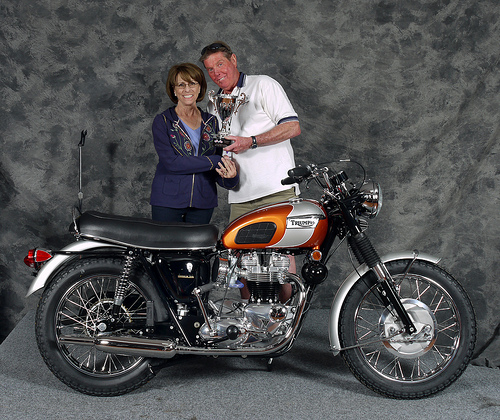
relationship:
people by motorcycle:
[154, 40, 300, 371] [21, 131, 479, 406]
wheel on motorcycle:
[28, 253, 177, 399] [21, 131, 479, 406]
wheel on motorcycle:
[335, 258, 479, 403] [21, 131, 479, 406]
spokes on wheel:
[56, 276, 151, 379] [28, 253, 177, 399]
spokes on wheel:
[356, 272, 467, 384] [335, 258, 479, 403]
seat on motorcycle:
[68, 209, 221, 256] [21, 131, 479, 406]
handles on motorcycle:
[281, 163, 322, 193] [21, 131, 479, 406]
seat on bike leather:
[68, 209, 221, 256] [101, 227, 189, 239]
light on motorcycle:
[355, 177, 392, 218] [21, 131, 479, 406]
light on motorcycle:
[22, 245, 56, 269] [21, 131, 479, 406]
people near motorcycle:
[154, 40, 300, 371] [21, 131, 479, 406]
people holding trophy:
[154, 40, 300, 371] [207, 87, 249, 151]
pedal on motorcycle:
[191, 279, 249, 347] [21, 131, 479, 406]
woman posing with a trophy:
[147, 59, 218, 351] [207, 87, 249, 151]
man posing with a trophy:
[202, 40, 303, 358] [207, 87, 249, 151]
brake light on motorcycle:
[22, 249, 33, 267] [21, 131, 479, 406]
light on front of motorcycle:
[355, 177, 392, 218] [21, 131, 479, 406]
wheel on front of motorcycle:
[335, 258, 479, 403] [21, 131, 479, 406]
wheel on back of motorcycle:
[28, 253, 177, 399] [21, 131, 479, 406]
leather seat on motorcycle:
[101, 227, 189, 239] [21, 131, 479, 406]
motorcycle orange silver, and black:
[21, 131, 479, 406] [81, 229, 96, 247]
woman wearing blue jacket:
[147, 59, 218, 351] [151, 107, 229, 206]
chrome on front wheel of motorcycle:
[410, 305, 430, 323] [21, 131, 479, 406]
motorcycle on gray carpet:
[21, 131, 479, 406] [0, 308, 488, 418]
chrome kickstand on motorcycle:
[262, 356, 280, 375] [21, 131, 479, 406]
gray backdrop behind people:
[1, 2, 499, 379] [154, 40, 300, 371]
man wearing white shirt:
[202, 40, 303, 358] [209, 71, 306, 202]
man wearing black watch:
[202, 40, 303, 358] [247, 134, 260, 152]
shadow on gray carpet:
[293, 344, 350, 393] [0, 308, 488, 418]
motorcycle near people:
[21, 131, 479, 406] [154, 40, 300, 371]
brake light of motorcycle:
[22, 249, 33, 267] [21, 131, 479, 406]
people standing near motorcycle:
[154, 40, 300, 371] [21, 131, 479, 406]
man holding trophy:
[202, 40, 303, 358] [207, 87, 249, 151]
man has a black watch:
[202, 40, 303, 358] [247, 134, 260, 152]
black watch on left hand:
[247, 134, 260, 152] [223, 132, 266, 156]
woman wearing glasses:
[147, 59, 218, 351] [172, 79, 207, 92]